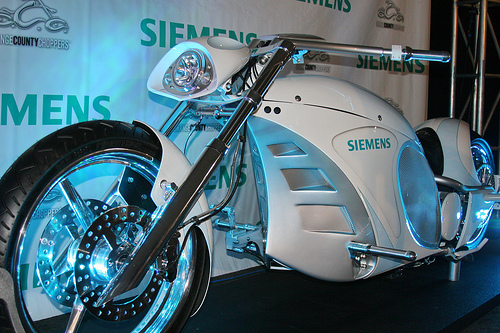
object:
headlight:
[145, 33, 253, 104]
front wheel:
[1, 110, 213, 330]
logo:
[138, 17, 258, 49]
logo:
[354, 52, 426, 74]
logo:
[299, 0, 351, 12]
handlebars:
[294, 39, 491, 100]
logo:
[0, 84, 120, 134]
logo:
[343, 136, 395, 153]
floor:
[233, 286, 316, 328]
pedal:
[356, 239, 423, 269]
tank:
[291, 68, 450, 271]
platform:
[4, 237, 484, 329]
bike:
[4, 32, 494, 329]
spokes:
[33, 169, 188, 326]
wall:
[3, 2, 434, 322]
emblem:
[0, 0, 73, 58]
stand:
[423, 238, 481, 299]